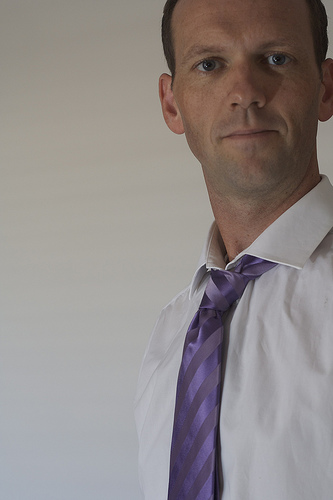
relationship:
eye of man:
[189, 43, 226, 83] [141, 8, 321, 238]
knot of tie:
[191, 267, 246, 319] [162, 257, 274, 462]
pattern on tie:
[184, 349, 229, 430] [162, 257, 274, 462]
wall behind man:
[23, 74, 166, 267] [141, 8, 321, 238]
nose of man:
[247, 78, 272, 108] [141, 8, 321, 238]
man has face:
[141, 8, 321, 238] [181, 32, 305, 178]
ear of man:
[112, 48, 191, 177] [141, 8, 321, 238]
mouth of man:
[233, 105, 284, 146] [141, 8, 321, 238]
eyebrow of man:
[256, 30, 299, 58] [141, 8, 321, 238]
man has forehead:
[141, 8, 321, 238] [184, 10, 279, 64]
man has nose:
[141, 8, 321, 238] [247, 78, 272, 108]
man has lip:
[141, 8, 321, 238] [222, 126, 277, 147]